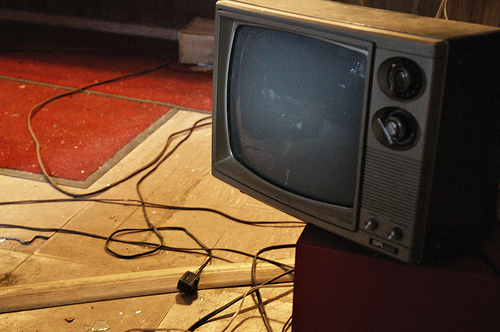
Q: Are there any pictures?
A: No, there are no pictures.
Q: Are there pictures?
A: No, there are no pictures.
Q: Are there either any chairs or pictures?
A: No, there are no pictures or chairs.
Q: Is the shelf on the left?
A: Yes, the shelf is on the left of the image.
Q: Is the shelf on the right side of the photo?
A: No, the shelf is on the left of the image.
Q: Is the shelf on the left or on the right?
A: The shelf is on the left of the image.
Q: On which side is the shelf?
A: The shelf is on the left of the image.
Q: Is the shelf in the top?
A: Yes, the shelf is in the top of the image.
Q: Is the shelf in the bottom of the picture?
A: No, the shelf is in the top of the image.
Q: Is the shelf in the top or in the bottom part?
A: The shelf is in the top of the image.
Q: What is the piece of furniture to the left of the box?
A: The piece of furniture is a shelf.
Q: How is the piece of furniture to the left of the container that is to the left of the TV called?
A: The piece of furniture is a shelf.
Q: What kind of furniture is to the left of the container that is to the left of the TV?
A: The piece of furniture is a shelf.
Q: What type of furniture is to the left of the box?
A: The piece of furniture is a shelf.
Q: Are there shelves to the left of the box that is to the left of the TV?
A: Yes, there is a shelf to the left of the box.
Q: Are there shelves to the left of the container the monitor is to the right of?
A: Yes, there is a shelf to the left of the box.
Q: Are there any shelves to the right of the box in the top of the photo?
A: No, the shelf is to the left of the box.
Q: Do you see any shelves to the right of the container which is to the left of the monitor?
A: No, the shelf is to the left of the box.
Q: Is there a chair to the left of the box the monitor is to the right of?
A: No, there is a shelf to the left of the box.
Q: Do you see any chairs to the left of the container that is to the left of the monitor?
A: No, there is a shelf to the left of the box.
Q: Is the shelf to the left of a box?
A: Yes, the shelf is to the left of a box.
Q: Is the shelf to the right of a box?
A: No, the shelf is to the left of a box.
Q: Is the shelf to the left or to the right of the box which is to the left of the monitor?
A: The shelf is to the left of the box.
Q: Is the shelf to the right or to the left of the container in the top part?
A: The shelf is to the left of the box.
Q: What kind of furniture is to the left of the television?
A: The piece of furniture is a shelf.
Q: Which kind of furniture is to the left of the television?
A: The piece of furniture is a shelf.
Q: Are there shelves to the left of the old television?
A: Yes, there is a shelf to the left of the TV.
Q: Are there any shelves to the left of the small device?
A: Yes, there is a shelf to the left of the TV.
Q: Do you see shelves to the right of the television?
A: No, the shelf is to the left of the television.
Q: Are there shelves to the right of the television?
A: No, the shelf is to the left of the television.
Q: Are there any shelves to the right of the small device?
A: No, the shelf is to the left of the television.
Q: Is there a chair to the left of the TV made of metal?
A: No, there is a shelf to the left of the TV.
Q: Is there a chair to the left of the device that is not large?
A: No, there is a shelf to the left of the TV.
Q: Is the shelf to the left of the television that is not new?
A: Yes, the shelf is to the left of the television.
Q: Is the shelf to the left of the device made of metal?
A: Yes, the shelf is to the left of the television.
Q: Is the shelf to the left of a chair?
A: No, the shelf is to the left of the television.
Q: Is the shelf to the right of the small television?
A: No, the shelf is to the left of the television.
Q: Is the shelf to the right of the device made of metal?
A: No, the shelf is to the left of the television.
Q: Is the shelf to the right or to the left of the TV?
A: The shelf is to the left of the TV.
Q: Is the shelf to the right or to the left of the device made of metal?
A: The shelf is to the left of the TV.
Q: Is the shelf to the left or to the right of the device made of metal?
A: The shelf is to the left of the TV.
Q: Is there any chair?
A: No, there are no chairs.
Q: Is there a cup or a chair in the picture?
A: No, there are no chairs or cups.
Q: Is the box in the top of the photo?
A: Yes, the box is in the top of the image.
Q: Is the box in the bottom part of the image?
A: No, the box is in the top of the image.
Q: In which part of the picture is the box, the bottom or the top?
A: The box is in the top of the image.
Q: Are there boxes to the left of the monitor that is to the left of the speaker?
A: Yes, there is a box to the left of the monitor.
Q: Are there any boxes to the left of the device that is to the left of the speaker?
A: Yes, there is a box to the left of the monitor.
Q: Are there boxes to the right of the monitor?
A: No, the box is to the left of the monitor.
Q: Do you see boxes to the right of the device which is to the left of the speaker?
A: No, the box is to the left of the monitor.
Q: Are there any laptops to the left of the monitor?
A: No, there is a box to the left of the monitor.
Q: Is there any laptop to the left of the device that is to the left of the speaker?
A: No, there is a box to the left of the monitor.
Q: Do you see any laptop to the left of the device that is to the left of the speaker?
A: No, there is a box to the left of the monitor.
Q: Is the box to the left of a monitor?
A: Yes, the box is to the left of a monitor.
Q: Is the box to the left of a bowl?
A: No, the box is to the left of a monitor.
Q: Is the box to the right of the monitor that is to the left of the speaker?
A: No, the box is to the left of the monitor.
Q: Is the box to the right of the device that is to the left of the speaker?
A: No, the box is to the left of the monitor.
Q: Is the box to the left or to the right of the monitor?
A: The box is to the left of the monitor.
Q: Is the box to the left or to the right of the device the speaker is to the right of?
A: The box is to the left of the monitor.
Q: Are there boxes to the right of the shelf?
A: Yes, there is a box to the right of the shelf.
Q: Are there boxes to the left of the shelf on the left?
A: No, the box is to the right of the shelf.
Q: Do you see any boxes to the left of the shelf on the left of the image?
A: No, the box is to the right of the shelf.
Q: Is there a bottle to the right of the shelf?
A: No, there is a box to the right of the shelf.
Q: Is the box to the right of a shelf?
A: Yes, the box is to the right of a shelf.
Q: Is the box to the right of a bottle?
A: No, the box is to the right of a shelf.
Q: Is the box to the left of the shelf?
A: No, the box is to the right of the shelf.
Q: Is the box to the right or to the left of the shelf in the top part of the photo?
A: The box is to the right of the shelf.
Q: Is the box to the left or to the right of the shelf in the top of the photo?
A: The box is to the right of the shelf.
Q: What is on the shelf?
A: The box is on the shelf.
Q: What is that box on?
A: The box is on the shelf.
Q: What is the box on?
A: The box is on the shelf.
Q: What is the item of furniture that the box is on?
A: The piece of furniture is a shelf.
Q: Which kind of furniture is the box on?
A: The box is on the shelf.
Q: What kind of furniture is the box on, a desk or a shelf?
A: The box is on a shelf.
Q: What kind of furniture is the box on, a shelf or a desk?
A: The box is on a shelf.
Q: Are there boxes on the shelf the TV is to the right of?
A: Yes, there is a box on the shelf.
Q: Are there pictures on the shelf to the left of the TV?
A: No, there is a box on the shelf.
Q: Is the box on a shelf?
A: Yes, the box is on a shelf.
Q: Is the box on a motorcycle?
A: No, the box is on a shelf.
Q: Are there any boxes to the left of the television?
A: Yes, there is a box to the left of the television.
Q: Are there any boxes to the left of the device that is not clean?
A: Yes, there is a box to the left of the television.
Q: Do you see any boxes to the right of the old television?
A: No, the box is to the left of the TV.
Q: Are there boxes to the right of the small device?
A: No, the box is to the left of the TV.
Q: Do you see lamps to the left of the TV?
A: No, there is a box to the left of the TV.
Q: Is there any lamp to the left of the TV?
A: No, there is a box to the left of the TV.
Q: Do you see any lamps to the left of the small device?
A: No, there is a box to the left of the TV.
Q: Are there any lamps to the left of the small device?
A: No, there is a box to the left of the TV.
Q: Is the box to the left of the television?
A: Yes, the box is to the left of the television.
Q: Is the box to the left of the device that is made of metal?
A: Yes, the box is to the left of the television.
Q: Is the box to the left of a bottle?
A: No, the box is to the left of the television.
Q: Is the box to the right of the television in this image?
A: No, the box is to the left of the television.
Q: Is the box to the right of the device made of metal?
A: No, the box is to the left of the television.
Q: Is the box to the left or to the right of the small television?
A: The box is to the left of the television.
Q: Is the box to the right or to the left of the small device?
A: The box is to the left of the television.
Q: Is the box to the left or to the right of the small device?
A: The box is to the left of the television.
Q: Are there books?
A: No, there are no books.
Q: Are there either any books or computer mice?
A: No, there are no books or computer mice.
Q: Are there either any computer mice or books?
A: No, there are no books or computer mice.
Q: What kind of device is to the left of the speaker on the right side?
A: The device is a monitor.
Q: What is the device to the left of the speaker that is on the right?
A: The device is a monitor.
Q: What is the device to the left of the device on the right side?
A: The device is a monitor.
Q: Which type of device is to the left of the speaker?
A: The device is a monitor.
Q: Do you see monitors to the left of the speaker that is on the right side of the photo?
A: Yes, there is a monitor to the left of the speaker.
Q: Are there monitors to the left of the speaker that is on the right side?
A: Yes, there is a monitor to the left of the speaker.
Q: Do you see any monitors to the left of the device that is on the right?
A: Yes, there is a monitor to the left of the speaker.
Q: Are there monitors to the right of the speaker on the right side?
A: No, the monitor is to the left of the speaker.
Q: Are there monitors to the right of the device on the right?
A: No, the monitor is to the left of the speaker.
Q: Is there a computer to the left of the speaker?
A: No, there is a monitor to the left of the speaker.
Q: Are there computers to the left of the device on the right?
A: No, there is a monitor to the left of the speaker.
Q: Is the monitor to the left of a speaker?
A: Yes, the monitor is to the left of a speaker.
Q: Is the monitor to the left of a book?
A: No, the monitor is to the left of a speaker.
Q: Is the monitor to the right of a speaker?
A: No, the monitor is to the left of a speaker.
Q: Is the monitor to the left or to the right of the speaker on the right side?
A: The monitor is to the left of the speaker.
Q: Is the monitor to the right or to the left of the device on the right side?
A: The monitor is to the left of the speaker.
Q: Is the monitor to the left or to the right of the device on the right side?
A: The monitor is to the left of the speaker.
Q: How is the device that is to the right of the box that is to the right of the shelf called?
A: The device is a monitor.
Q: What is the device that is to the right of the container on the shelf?
A: The device is a monitor.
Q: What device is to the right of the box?
A: The device is a monitor.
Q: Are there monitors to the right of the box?
A: Yes, there is a monitor to the right of the box.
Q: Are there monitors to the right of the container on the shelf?
A: Yes, there is a monitor to the right of the box.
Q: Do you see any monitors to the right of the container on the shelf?
A: Yes, there is a monitor to the right of the box.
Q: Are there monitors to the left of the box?
A: No, the monitor is to the right of the box.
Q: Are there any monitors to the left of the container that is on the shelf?
A: No, the monitor is to the right of the box.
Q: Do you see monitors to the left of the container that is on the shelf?
A: No, the monitor is to the right of the box.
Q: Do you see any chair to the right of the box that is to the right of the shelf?
A: No, there is a monitor to the right of the box.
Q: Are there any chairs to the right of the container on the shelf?
A: No, there is a monitor to the right of the box.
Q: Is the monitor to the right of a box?
A: Yes, the monitor is to the right of a box.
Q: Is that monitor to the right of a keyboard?
A: No, the monitor is to the right of a box.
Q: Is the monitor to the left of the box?
A: No, the monitor is to the right of the box.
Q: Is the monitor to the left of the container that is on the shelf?
A: No, the monitor is to the right of the box.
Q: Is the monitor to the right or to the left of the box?
A: The monitor is to the right of the box.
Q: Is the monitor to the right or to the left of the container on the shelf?
A: The monitor is to the right of the box.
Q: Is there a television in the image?
A: Yes, there is a television.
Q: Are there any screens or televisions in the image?
A: Yes, there is a television.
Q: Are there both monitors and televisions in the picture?
A: Yes, there are both a television and a monitor.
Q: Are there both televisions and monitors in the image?
A: Yes, there are both a television and a monitor.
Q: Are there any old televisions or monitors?
A: Yes, there is an old television.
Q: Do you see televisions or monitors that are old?
A: Yes, the television is old.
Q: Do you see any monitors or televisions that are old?
A: Yes, the television is old.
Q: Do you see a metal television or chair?
A: Yes, there is a metal television.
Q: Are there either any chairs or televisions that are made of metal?
A: Yes, the television is made of metal.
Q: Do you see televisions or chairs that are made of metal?
A: Yes, the television is made of metal.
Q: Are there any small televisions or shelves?
A: Yes, there is a small television.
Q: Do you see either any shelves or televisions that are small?
A: Yes, the television is small.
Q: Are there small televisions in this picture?
A: Yes, there is a small television.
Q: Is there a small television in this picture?
A: Yes, there is a small television.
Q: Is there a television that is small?
A: Yes, there is a television that is small.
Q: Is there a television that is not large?
A: Yes, there is a small television.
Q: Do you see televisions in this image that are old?
A: Yes, there is an old television.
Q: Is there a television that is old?
A: Yes, there is a television that is old.